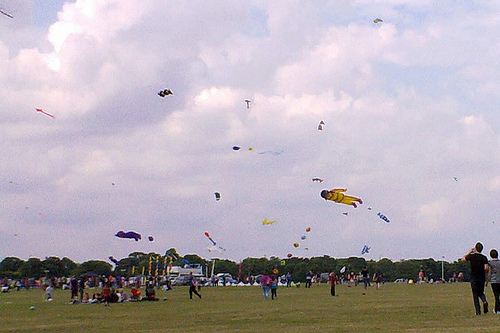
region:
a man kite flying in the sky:
[315, 187, 372, 216]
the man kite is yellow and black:
[314, 187, 365, 207]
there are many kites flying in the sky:
[9, 3, 486, 237]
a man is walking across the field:
[186, 269, 206, 301]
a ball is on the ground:
[26, 303, 38, 317]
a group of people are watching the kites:
[7, 275, 35, 292]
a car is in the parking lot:
[248, 274, 265, 283]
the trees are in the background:
[2, 257, 464, 283]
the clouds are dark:
[5, 3, 496, 250]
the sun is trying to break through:
[46, 3, 101, 55]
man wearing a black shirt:
[464, 232, 491, 321]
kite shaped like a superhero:
[304, 183, 386, 212]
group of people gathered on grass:
[41, 271, 191, 311]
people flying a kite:
[254, 178, 362, 311]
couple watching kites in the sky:
[455, 233, 498, 323]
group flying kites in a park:
[44, 188, 221, 317]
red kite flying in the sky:
[19, 86, 66, 137]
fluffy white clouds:
[45, 5, 149, 96]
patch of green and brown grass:
[369, 285, 450, 326]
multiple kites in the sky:
[141, 71, 413, 243]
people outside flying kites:
[102, 149, 270, 306]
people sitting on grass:
[63, 264, 175, 306]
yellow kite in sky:
[312, 186, 379, 223]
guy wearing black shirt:
[448, 236, 498, 313]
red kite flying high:
[29, 101, 72, 145]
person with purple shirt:
[255, 272, 274, 297]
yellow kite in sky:
[250, 213, 288, 230]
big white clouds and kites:
[35, 23, 332, 184]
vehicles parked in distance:
[167, 261, 321, 301]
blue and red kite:
[192, 222, 244, 258]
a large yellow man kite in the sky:
[319, 183, 367, 214]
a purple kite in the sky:
[113, 228, 148, 242]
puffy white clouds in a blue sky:
[5, 6, 488, 256]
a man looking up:
[464, 241, 490, 309]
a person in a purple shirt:
[258, 269, 268, 296]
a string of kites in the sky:
[262, 215, 324, 289]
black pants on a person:
[184, 267, 202, 301]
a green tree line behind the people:
[6, 249, 492, 283]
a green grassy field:
[5, 276, 499, 331]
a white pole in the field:
[437, 253, 447, 285]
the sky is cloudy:
[132, 135, 291, 270]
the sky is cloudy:
[86, 51, 343, 233]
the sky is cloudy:
[110, 80, 383, 184]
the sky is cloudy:
[65, 57, 230, 180]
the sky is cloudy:
[92, 9, 365, 163]